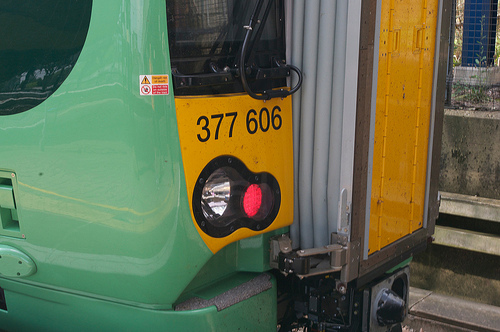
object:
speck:
[36, 170, 49, 177]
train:
[0, 0, 458, 332]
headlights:
[191, 161, 246, 238]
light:
[242, 185, 269, 220]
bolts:
[16, 259, 23, 265]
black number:
[244, 108, 259, 136]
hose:
[234, 0, 312, 102]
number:
[223, 111, 238, 139]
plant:
[470, 12, 491, 107]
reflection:
[49, 165, 163, 242]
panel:
[0, 1, 283, 331]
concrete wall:
[409, 110, 499, 309]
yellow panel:
[175, 87, 293, 254]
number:
[211, 113, 226, 140]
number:
[258, 107, 269, 132]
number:
[271, 105, 281, 130]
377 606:
[194, 105, 284, 144]